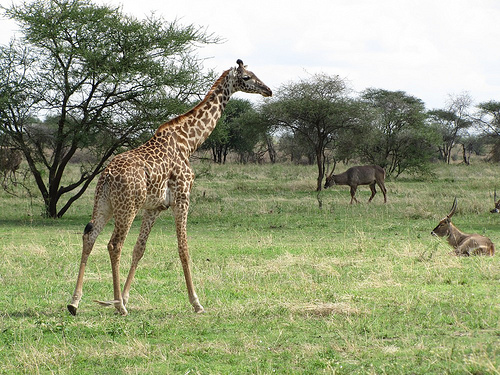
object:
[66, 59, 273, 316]
giraffe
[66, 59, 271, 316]
animal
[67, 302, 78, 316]
tip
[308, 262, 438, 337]
grass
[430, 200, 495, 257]
animal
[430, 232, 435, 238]
nose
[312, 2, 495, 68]
clouds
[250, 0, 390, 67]
sky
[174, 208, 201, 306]
leg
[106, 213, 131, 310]
leg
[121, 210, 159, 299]
leg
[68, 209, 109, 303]
leg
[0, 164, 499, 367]
ground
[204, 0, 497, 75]
cloud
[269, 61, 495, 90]
cloud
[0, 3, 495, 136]
sky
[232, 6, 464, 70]
sky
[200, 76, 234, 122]
neck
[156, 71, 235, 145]
neck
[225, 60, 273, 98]
head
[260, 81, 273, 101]
mouth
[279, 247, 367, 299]
grass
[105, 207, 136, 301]
legs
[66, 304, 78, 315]
hoof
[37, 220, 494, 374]
grass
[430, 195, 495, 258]
animal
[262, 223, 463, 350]
grass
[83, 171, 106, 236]
giraffes tail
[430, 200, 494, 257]
gazelle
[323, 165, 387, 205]
animal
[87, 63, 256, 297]
giraffe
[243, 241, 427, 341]
grassy area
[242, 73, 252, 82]
eye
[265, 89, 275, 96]
nose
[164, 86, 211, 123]
hair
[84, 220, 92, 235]
hair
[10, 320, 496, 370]
grass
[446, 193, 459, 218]
horns